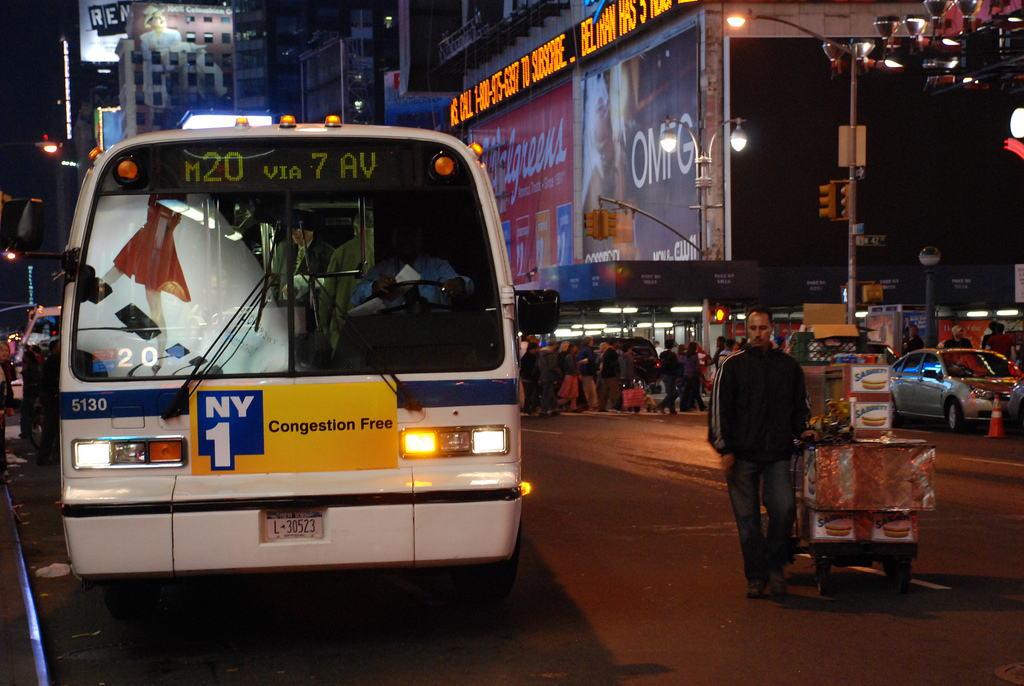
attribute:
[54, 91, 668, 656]
bus — white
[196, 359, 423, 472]
sign — yellow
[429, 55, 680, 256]
billboard — red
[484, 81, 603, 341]
lettering — white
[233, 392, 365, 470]
lettering — white, blue, black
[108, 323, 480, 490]
sign — yellow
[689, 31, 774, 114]
light — yellow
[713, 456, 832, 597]
jeans — blue